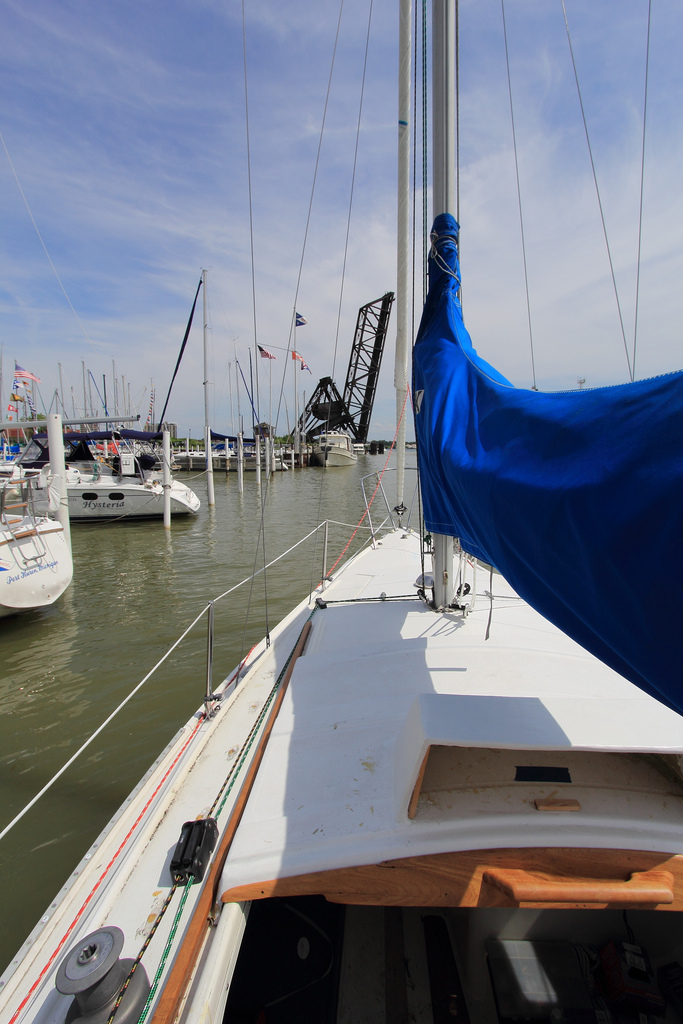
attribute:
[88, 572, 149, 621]
water — still, green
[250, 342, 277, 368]
flag — colorful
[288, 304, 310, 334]
flag — colorful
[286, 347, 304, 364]
flag — colorful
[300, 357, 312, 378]
flag — colorful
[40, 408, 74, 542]
pole — white, tall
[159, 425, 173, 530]
pole — tall, white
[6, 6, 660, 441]
clouds — white, thin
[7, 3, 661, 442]
sky — blue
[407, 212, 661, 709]
canvas — blue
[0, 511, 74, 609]
boat — white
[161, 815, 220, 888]
contraption — black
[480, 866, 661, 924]
handle — wooden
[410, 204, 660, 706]
fabric — blue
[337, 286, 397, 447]
bridge — lifted